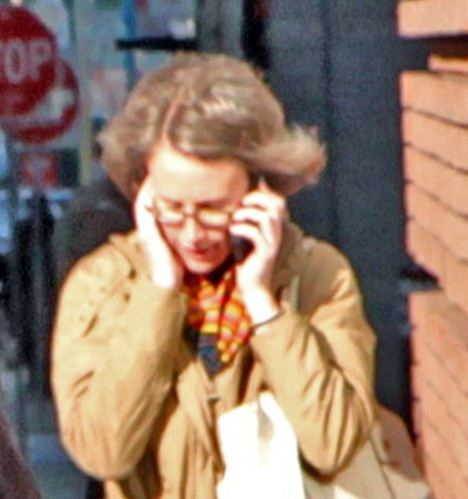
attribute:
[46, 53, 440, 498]
woman — standing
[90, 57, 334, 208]
hair — brown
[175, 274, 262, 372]
scarf — colorful, orange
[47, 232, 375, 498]
jacket — tan, brown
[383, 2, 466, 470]
wall — red